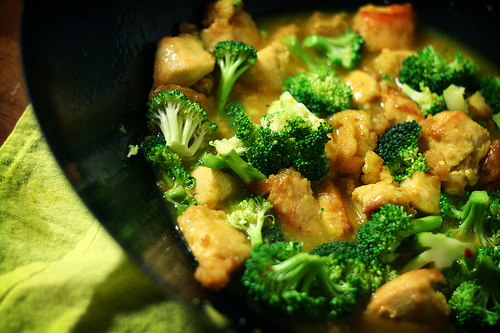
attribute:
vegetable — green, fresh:
[232, 192, 437, 309]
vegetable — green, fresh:
[142, 75, 322, 184]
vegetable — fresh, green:
[178, 54, 434, 217]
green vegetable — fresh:
[401, 38, 483, 119]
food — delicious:
[155, 41, 490, 328]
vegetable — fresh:
[433, 190, 498, 250]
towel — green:
[4, 98, 183, 330]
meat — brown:
[369, 268, 453, 330]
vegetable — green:
[147, 87, 219, 147]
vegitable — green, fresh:
[446, 280, 498, 324]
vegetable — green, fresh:
[17, 59, 495, 331]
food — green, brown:
[144, 4, 499, 322]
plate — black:
[15, 0, 493, 331]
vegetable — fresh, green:
[212, 40, 257, 114]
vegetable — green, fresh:
[372, 119, 426, 182]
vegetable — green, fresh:
[147, 88, 214, 165]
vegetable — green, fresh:
[240, 238, 355, 324]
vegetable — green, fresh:
[434, 183, 498, 249]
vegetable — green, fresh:
[339, 198, 431, 273]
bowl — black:
[17, 2, 498, 329]